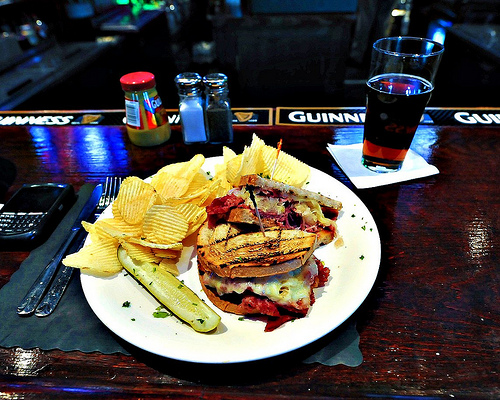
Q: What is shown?
A: Food.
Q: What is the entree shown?
A: Sandwich.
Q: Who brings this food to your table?
A: Waitress.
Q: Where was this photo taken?
A: Restaurant.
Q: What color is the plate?
A: White.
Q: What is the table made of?
A: Wood.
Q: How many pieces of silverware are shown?
A: Two.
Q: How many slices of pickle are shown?
A: One.